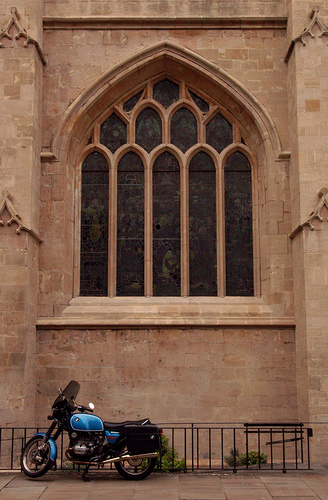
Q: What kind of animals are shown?
A: None.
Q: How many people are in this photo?
A: None.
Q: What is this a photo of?
A: A motorcycle.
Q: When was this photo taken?
A: Daytime.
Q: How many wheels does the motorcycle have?
A: Two.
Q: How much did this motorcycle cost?
A: It is impossible to know this.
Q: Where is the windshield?
A: On the front of the motorcycle.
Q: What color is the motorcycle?
A: Blue.